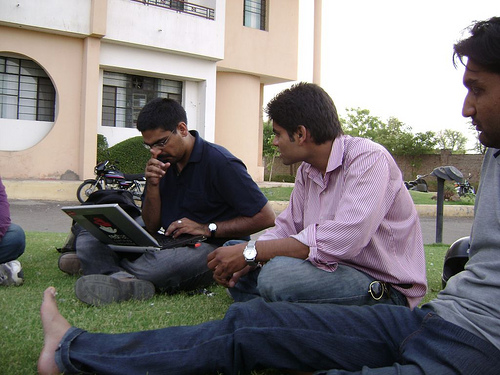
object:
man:
[56, 98, 277, 310]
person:
[0, 180, 33, 288]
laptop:
[60, 203, 206, 255]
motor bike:
[73, 160, 144, 205]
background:
[0, 0, 499, 375]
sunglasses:
[139, 138, 174, 152]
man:
[204, 82, 428, 303]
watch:
[241, 239, 260, 268]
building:
[0, 0, 297, 201]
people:
[37, 17, 500, 375]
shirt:
[257, 132, 430, 311]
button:
[319, 189, 330, 197]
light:
[427, 164, 465, 243]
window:
[0, 51, 60, 120]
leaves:
[356, 109, 397, 143]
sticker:
[81, 216, 135, 244]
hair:
[134, 97, 190, 135]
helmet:
[437, 235, 474, 289]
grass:
[0, 232, 452, 375]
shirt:
[420, 134, 499, 355]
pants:
[53, 297, 499, 374]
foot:
[34, 285, 81, 374]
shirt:
[143, 129, 268, 246]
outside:
[0, 0, 499, 375]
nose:
[149, 147, 162, 158]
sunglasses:
[365, 280, 395, 300]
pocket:
[368, 281, 393, 302]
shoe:
[71, 270, 157, 306]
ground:
[0, 198, 499, 375]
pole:
[311, 0, 322, 85]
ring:
[175, 218, 186, 226]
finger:
[164, 222, 190, 238]